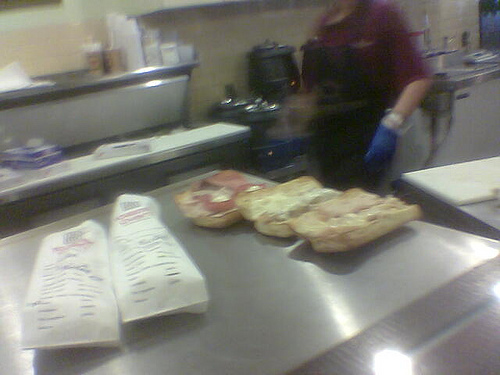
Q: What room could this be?
A: It is a kitchen.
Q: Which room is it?
A: It is a kitchen.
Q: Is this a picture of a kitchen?
A: Yes, it is showing a kitchen.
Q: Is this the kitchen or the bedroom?
A: It is the kitchen.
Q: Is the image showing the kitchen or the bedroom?
A: It is showing the kitchen.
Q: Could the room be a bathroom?
A: No, it is a kitchen.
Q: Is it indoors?
A: Yes, it is indoors.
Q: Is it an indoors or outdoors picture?
A: It is indoors.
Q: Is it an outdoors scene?
A: No, it is indoors.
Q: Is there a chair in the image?
A: No, there are no chairs.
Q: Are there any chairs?
A: No, there are no chairs.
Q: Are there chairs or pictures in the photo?
A: No, there are no chairs or pictures.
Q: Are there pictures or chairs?
A: No, there are no chairs or pictures.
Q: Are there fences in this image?
A: No, there are no fences.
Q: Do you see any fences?
A: No, there are no fences.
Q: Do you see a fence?
A: No, there are no fences.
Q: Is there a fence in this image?
A: No, there are no fences.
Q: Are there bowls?
A: No, there are no bowls.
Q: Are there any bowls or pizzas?
A: No, there are no bowls or pizzas.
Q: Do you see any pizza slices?
A: No, there are no pizza slices.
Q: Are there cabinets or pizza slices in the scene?
A: No, there are no pizza slices or cabinets.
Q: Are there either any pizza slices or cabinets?
A: No, there are no pizza slices or cabinets.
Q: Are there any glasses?
A: No, there are no glasses.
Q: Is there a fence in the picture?
A: No, there are no fences.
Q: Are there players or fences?
A: No, there are no fences or players.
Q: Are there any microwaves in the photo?
A: No, there are no microwaves.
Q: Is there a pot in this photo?
A: Yes, there is a pot.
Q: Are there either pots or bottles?
A: Yes, there is a pot.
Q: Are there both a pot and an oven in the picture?
A: No, there is a pot but no ovens.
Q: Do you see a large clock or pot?
A: Yes, there is a large pot.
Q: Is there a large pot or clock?
A: Yes, there is a large pot.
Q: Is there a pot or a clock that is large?
A: Yes, the pot is large.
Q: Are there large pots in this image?
A: Yes, there is a large pot.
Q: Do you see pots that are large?
A: Yes, there is a pot that is large.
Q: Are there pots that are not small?
A: Yes, there is a large pot.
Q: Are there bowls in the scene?
A: No, there are no bowls.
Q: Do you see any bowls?
A: No, there are no bowls.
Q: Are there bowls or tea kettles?
A: No, there are no bowls or tea kettles.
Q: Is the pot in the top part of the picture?
A: Yes, the pot is in the top of the image.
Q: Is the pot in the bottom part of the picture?
A: No, the pot is in the top of the image.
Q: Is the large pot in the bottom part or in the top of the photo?
A: The pot is in the top of the image.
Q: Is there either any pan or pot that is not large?
A: No, there is a pot but it is large.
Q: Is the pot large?
A: Yes, the pot is large.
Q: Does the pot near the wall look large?
A: Yes, the pot is large.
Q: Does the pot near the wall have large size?
A: Yes, the pot is large.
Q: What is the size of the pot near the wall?
A: The pot is large.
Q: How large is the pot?
A: The pot is large.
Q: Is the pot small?
A: No, the pot is large.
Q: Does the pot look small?
A: No, the pot is large.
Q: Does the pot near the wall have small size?
A: No, the pot is large.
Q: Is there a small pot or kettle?
A: No, there is a pot but it is large.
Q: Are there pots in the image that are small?
A: No, there is a pot but it is large.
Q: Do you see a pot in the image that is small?
A: No, there is a pot but it is large.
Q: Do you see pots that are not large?
A: No, there is a pot but it is large.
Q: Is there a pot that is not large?
A: No, there is a pot but it is large.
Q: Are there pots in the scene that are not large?
A: No, there is a pot but it is large.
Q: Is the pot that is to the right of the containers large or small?
A: The pot is large.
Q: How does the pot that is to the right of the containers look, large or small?
A: The pot is large.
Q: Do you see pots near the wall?
A: Yes, there is a pot near the wall.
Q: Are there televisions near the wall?
A: No, there is a pot near the wall.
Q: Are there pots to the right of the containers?
A: Yes, there is a pot to the right of the containers.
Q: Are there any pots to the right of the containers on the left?
A: Yes, there is a pot to the right of the containers.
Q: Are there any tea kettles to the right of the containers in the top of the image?
A: No, there is a pot to the right of the containers.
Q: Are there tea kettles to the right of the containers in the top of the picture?
A: No, there is a pot to the right of the containers.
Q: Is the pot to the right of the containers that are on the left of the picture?
A: Yes, the pot is to the right of the containers.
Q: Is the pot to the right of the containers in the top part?
A: Yes, the pot is to the right of the containers.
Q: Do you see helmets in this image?
A: No, there are no helmets.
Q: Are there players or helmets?
A: No, there are no helmets or players.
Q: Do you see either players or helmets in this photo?
A: No, there are no helmets or players.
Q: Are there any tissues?
A: No, there are no tissues.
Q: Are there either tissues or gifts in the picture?
A: No, there are no tissues or gifts.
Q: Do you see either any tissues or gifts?
A: No, there are no tissues or gifts.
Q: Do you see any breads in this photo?
A: Yes, there is a bread.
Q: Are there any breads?
A: Yes, there is a bread.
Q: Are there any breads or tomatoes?
A: Yes, there is a bread.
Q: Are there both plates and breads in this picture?
A: No, there is a bread but no plates.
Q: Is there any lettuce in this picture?
A: No, there is no lettuce.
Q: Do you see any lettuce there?
A: No, there is no lettuce.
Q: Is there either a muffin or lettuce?
A: No, there are no lettuce or muffins.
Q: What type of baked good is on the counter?
A: The food is a bread.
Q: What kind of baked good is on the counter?
A: The food is a bread.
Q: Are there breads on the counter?
A: Yes, there is a bread on the counter.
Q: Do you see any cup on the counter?
A: No, there is a bread on the counter.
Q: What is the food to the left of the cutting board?
A: The food is a bread.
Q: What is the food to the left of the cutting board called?
A: The food is a bread.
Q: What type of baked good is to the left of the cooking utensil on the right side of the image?
A: The food is a bread.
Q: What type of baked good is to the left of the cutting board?
A: The food is a bread.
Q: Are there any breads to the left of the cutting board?
A: Yes, there is a bread to the left of the cutting board.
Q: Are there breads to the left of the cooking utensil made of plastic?
A: Yes, there is a bread to the left of the cutting board.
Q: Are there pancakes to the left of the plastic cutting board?
A: No, there is a bread to the left of the cutting board.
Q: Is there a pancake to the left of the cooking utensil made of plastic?
A: No, there is a bread to the left of the cutting board.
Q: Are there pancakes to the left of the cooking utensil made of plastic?
A: No, there is a bread to the left of the cutting board.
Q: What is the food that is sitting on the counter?
A: The food is a bread.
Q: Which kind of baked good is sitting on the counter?
A: The food is a bread.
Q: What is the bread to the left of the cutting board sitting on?
A: The bread is sitting on the counter.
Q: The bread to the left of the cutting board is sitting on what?
A: The bread is sitting on the counter.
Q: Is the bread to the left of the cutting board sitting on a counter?
A: Yes, the bread is sitting on a counter.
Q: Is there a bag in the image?
A: Yes, there is a bag.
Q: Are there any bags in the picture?
A: Yes, there is a bag.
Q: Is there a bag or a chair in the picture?
A: Yes, there is a bag.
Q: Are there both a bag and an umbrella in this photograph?
A: No, there is a bag but no umbrellas.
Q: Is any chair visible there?
A: No, there are no chairs.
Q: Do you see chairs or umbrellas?
A: No, there are no chairs or umbrellas.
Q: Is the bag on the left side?
A: Yes, the bag is on the left of the image.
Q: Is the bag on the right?
A: No, the bag is on the left of the image.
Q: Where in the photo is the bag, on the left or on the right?
A: The bag is on the left of the image.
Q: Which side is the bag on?
A: The bag is on the left of the image.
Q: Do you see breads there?
A: Yes, there is a bread.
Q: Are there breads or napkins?
A: Yes, there is a bread.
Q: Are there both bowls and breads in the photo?
A: No, there is a bread but no bowls.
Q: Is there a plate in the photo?
A: No, there are no plates.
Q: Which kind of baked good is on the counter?
A: The food is a bread.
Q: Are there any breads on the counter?
A: Yes, there is a bread on the counter.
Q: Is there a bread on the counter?
A: Yes, there is a bread on the counter.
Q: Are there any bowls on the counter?
A: No, there is a bread on the counter.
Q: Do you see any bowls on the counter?
A: No, there is a bread on the counter.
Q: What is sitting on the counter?
A: The bread is sitting on the counter.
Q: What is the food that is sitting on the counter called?
A: The food is a bread.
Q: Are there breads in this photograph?
A: Yes, there is a bread.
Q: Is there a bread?
A: Yes, there is a bread.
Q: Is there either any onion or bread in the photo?
A: Yes, there is a bread.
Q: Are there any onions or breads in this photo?
A: Yes, there is a bread.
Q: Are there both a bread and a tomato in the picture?
A: No, there is a bread but no tomatoes.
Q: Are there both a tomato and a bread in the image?
A: No, there is a bread but no tomatoes.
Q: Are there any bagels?
A: No, there are no bagels.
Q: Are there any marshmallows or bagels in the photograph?
A: No, there are no bagels or marshmallows.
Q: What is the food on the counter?
A: The food is a bread.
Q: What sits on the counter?
A: The bread sits on the counter.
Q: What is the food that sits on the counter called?
A: The food is a bread.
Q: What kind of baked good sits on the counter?
A: The food is a bread.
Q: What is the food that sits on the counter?
A: The food is a bread.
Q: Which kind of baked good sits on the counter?
A: The food is a bread.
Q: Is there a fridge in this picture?
A: No, there are no refrigerators.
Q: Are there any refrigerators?
A: No, there are no refrigerators.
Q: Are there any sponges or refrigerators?
A: No, there are no refrigerators or sponges.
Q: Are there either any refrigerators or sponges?
A: No, there are no refrigerators or sponges.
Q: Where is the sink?
A: The sink is in the kitchen.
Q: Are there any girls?
A: No, there are no girls.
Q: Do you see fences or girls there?
A: No, there are no girls or fences.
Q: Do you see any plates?
A: No, there are no plates.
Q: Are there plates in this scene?
A: No, there are no plates.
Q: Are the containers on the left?
A: Yes, the containers are on the left of the image.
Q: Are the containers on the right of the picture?
A: No, the containers are on the left of the image.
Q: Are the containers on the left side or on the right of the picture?
A: The containers are on the left of the image.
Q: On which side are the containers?
A: The containers are on the left of the image.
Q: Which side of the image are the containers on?
A: The containers are on the left of the image.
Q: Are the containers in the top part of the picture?
A: Yes, the containers are in the top of the image.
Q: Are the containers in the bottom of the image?
A: No, the containers are in the top of the image.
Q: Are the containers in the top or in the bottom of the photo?
A: The containers are in the top of the image.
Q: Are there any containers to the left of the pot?
A: Yes, there are containers to the left of the pot.